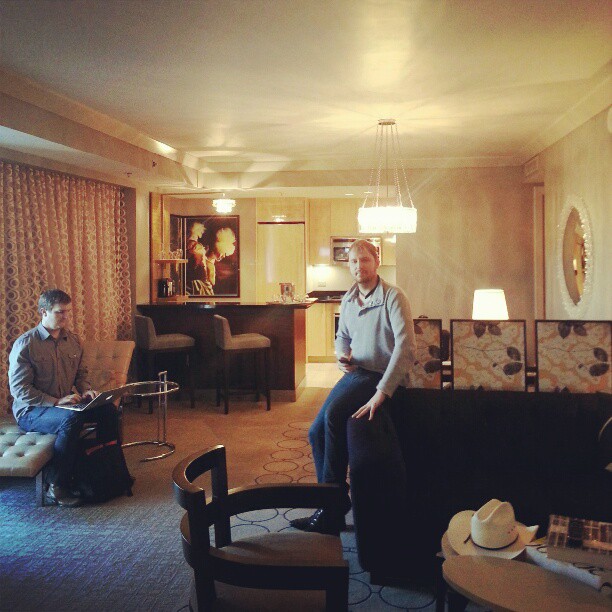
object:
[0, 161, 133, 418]
curtain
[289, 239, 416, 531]
man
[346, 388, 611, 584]
chair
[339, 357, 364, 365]
phone